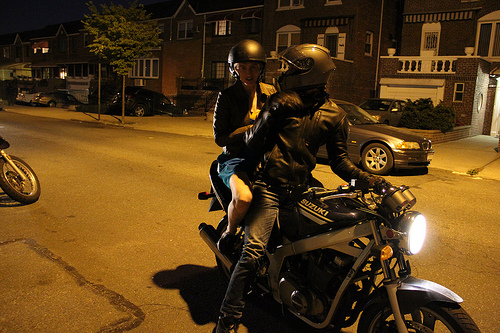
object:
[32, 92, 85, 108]
vehicles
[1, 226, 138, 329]
street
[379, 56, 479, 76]
balcony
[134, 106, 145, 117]
wheel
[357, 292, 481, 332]
tire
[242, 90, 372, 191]
jacket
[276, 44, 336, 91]
helmet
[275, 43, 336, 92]
head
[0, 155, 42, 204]
tire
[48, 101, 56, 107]
wheel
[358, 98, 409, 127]
car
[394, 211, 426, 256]
headlight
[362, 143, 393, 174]
tire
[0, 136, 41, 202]
bike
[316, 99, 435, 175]
vehicles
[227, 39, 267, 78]
helmet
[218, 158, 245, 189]
short pants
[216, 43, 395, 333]
driver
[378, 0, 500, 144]
building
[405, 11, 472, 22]
stripe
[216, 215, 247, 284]
tire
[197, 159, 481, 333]
bike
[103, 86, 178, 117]
bmw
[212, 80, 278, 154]
jacket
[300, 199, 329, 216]
name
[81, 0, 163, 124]
tree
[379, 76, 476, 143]
garage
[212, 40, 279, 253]
passenger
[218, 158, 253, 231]
leg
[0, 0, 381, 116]
building